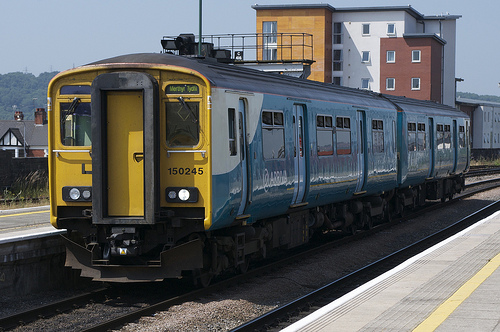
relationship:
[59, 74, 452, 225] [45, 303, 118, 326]
train on tracks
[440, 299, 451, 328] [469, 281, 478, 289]
line on cement yellow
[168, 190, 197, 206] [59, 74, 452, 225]
headlights of train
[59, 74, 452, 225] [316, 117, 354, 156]
train has two windows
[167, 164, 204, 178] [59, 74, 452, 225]
numbers on front of train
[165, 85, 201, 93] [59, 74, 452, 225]
digital front of train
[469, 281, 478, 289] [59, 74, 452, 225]
yellow door on train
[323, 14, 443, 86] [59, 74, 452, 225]
building behind train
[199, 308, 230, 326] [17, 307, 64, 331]
rocks are grey on track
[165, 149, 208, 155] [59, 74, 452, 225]
silver handles on train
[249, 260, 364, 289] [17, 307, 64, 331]
shadow cast on track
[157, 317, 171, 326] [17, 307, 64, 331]
pebbles on track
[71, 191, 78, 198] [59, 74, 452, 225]
white light on train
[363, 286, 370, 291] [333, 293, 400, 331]
white line on platform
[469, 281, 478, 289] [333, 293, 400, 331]
yellow line on platform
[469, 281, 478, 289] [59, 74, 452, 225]
yellow on front of train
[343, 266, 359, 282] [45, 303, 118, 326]
blue on train tracks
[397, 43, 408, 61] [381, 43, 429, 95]
red building small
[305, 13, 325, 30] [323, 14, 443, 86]
orange tall building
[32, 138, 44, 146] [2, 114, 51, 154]
grey roof on house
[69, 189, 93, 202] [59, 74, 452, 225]
light on train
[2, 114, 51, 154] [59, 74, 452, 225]
house near train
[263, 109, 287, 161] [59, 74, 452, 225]
window on train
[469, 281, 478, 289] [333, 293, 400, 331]
yellow stripe on platform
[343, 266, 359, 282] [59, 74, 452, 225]
blue on paint train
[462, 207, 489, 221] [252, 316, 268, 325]
rails made of steel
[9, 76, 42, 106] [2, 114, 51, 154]
hill behind house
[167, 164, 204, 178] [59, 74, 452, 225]
numbers on train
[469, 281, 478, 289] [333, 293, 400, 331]
yellow line marking platform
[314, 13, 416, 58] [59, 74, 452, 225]
colorful building behind train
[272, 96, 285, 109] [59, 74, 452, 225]
blue cars of train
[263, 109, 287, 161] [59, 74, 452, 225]
window on blue train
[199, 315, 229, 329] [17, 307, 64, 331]
gravel on train track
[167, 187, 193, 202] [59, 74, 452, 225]
headlight on train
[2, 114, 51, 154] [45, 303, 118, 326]
house near tracks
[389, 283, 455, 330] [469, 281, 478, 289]
ground grey with yellow